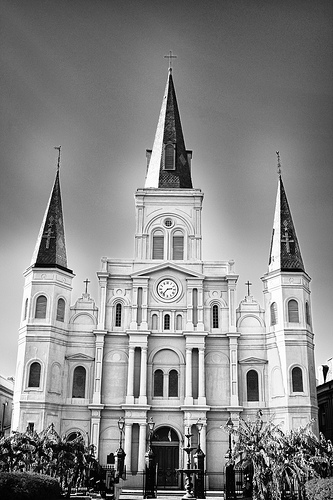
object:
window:
[152, 368, 165, 399]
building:
[8, 47, 322, 499]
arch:
[163, 313, 171, 332]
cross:
[161, 48, 177, 68]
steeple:
[142, 48, 192, 191]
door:
[146, 421, 182, 491]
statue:
[174, 425, 202, 499]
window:
[71, 364, 88, 399]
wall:
[100, 333, 129, 405]